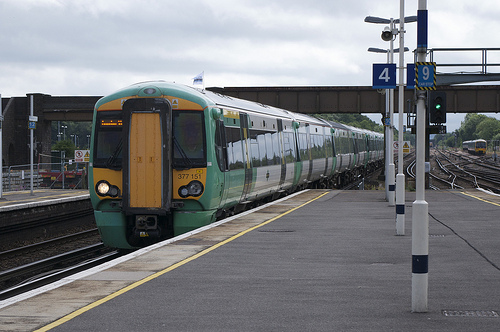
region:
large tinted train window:
[168, 107, 204, 168]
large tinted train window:
[92, 112, 124, 171]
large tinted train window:
[225, 126, 245, 168]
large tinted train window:
[248, 128, 258, 165]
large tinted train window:
[258, 130, 265, 162]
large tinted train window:
[263, 130, 273, 162]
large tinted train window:
[272, 130, 284, 162]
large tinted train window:
[279, 129, 290, 161]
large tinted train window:
[290, 128, 297, 160]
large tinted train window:
[295, 131, 307, 160]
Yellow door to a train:
[123, 101, 167, 213]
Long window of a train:
[223, 120, 250, 182]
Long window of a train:
[241, 116, 289, 172]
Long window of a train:
[279, 111, 305, 179]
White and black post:
[408, 179, 430, 322]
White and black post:
[395, 161, 408, 231]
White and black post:
[376, 165, 396, 205]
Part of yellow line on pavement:
[30, 302, 82, 327]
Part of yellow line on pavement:
[80, 292, 116, 310]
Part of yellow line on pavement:
[114, 255, 174, 292]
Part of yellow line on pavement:
[45, 296, 115, 330]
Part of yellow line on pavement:
[96, 272, 152, 314]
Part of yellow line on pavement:
[130, 256, 194, 299]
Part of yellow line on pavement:
[172, 243, 209, 277]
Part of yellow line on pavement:
[195, 234, 232, 275]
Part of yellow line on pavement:
[220, 218, 255, 255]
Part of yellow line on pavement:
[253, 205, 280, 233]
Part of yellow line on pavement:
[277, 199, 313, 223]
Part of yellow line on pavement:
[300, 185, 349, 220]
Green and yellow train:
[90, 61, 396, 190]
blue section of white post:
[402, 246, 437, 272]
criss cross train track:
[438, 151, 483, 173]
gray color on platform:
[231, 249, 341, 289]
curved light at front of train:
[174, 177, 216, 200]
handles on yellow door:
[132, 152, 159, 162]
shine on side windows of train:
[227, 115, 329, 167]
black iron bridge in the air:
[257, 68, 377, 114]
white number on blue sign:
[364, 57, 404, 92]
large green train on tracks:
[104, 77, 371, 209]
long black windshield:
[166, 127, 200, 170]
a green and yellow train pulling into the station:
[81, 82, 376, 233]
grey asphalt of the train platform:
[264, 245, 353, 300]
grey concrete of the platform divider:
[119, 254, 158, 274]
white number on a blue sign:
[376, 67, 393, 84]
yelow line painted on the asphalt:
[131, 248, 206, 295]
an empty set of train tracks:
[23, 228, 75, 273]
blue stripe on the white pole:
[408, 247, 430, 278]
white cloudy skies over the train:
[180, 23, 310, 73]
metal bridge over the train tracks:
[47, 84, 378, 118]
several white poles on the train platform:
[369, 126, 435, 308]